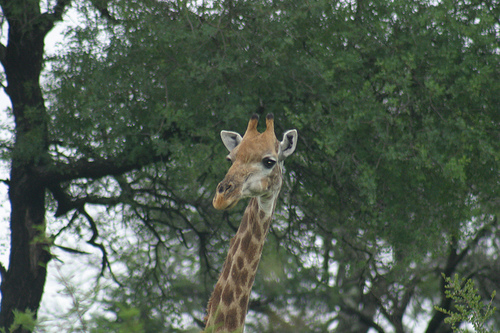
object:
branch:
[46, 177, 207, 285]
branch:
[40, 1, 72, 36]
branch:
[40, 122, 182, 202]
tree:
[136, 30, 488, 188]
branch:
[50, 32, 334, 177]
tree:
[2, 2, 376, 320]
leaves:
[427, 257, 498, 331]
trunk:
[0, 60, 113, 315]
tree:
[3, 0, 58, 322]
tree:
[335, 152, 487, 320]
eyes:
[209, 143, 246, 166]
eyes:
[260, 145, 317, 187]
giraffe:
[153, 117, 345, 303]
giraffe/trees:
[166, 44, 350, 330]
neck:
[204, 199, 281, 331]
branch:
[371, 31, 465, 158]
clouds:
[47, 27, 104, 54]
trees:
[46, 0, 214, 200]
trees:
[305, 0, 499, 275]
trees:
[181, 0, 323, 95]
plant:
[419, 266, 484, 328]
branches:
[52, 119, 188, 247]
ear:
[276, 122, 299, 162]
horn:
[265, 110, 273, 133]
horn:
[242, 105, 258, 134]